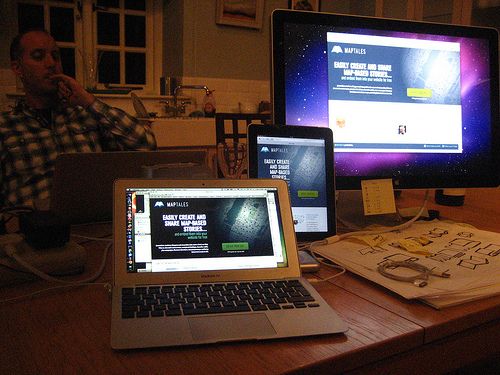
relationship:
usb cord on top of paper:
[382, 250, 432, 287] [434, 272, 477, 296]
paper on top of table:
[364, 238, 482, 249] [341, 290, 380, 336]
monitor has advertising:
[271, 12, 479, 171] [335, 53, 454, 138]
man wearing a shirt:
[0, 22, 160, 219] [19, 135, 49, 169]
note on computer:
[358, 171, 398, 215] [276, 25, 484, 205]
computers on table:
[108, 175, 351, 352] [339, 292, 386, 348]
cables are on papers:
[332, 225, 427, 295] [436, 230, 482, 299]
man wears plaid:
[6, 18, 155, 205] [10, 122, 59, 157]